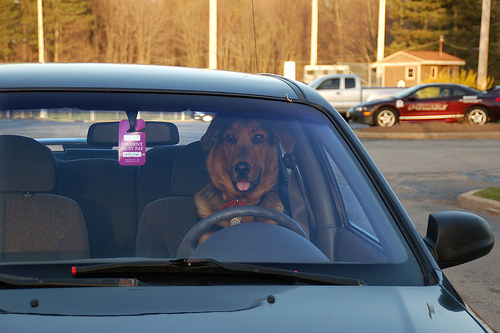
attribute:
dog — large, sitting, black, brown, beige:
[193, 117, 295, 253]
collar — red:
[219, 201, 256, 222]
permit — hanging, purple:
[117, 119, 147, 166]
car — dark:
[0, 62, 498, 332]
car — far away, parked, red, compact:
[345, 82, 499, 124]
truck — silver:
[307, 72, 413, 113]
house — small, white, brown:
[371, 36, 466, 87]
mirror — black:
[422, 212, 492, 270]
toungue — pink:
[236, 181, 251, 192]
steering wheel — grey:
[176, 203, 309, 258]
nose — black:
[236, 163, 251, 176]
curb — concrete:
[456, 189, 499, 209]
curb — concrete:
[357, 127, 499, 141]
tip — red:
[70, 268, 77, 276]